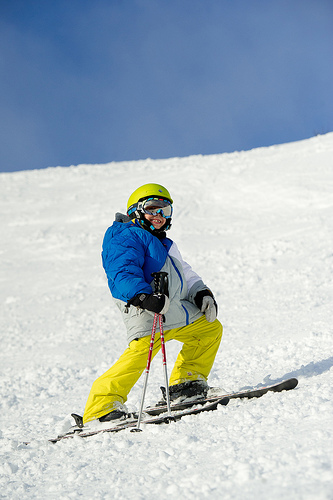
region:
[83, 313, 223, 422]
Ski pants are yellow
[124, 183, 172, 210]
Helmet is yellow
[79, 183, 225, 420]
Young boy holding ski pole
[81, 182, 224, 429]
Young boy standing in skis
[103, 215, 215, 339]
Jacket is blue and gray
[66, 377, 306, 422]
Long ski in snow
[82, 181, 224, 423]
Young boy is smiling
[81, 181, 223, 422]
Young man is smiling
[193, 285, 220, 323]
Glove is gray and black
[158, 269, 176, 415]
Ski pole is gray and red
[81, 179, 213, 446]
a child in the snow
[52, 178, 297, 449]
a child on skis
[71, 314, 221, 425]
yellow snow pants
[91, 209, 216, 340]
a blue and grey winter coat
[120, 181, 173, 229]
a hard yellow helmet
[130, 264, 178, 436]
two red and silver ski poles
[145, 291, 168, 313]
a black and white winter glove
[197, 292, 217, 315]
a black and white winter glove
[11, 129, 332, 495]
a white snowy hill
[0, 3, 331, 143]
a clear blue sky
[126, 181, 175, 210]
lime colored helmet on the young skiers head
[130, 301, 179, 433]
two ski poles in the snow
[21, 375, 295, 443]
skis attached to the boy's feet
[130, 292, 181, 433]
silver and red poles in the boy's hand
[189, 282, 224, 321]
black and gray gloves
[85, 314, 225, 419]
yellow pants on the skier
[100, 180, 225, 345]
skier wearing a blue and gray coat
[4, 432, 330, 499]
snow on the ground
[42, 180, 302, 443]
young person on skis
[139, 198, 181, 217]
goggles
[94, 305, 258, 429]
Skier wearing yellow pants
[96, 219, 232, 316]
Skier wearing blue jacket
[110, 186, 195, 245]
Skier wearing yellow helmet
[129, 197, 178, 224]
Skier wearing blue goggles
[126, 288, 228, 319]
Skier wearing ski gloves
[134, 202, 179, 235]
Skier has a big smile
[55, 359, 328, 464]
Skis and boots are black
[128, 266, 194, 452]
Two red ski poles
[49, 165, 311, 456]
A lot of snow on the ground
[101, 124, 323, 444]
Large hill covered with snow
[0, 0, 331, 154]
the sky is blue.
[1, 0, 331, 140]
the sky is clear.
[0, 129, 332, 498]
snow covering the ground.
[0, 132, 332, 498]
the snow is white.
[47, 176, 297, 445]
the kid is skiing.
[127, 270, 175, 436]
child holding ski poles.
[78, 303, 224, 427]
child's pants are yellow.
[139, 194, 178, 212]
goggles on child's face.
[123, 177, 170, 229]
child wearing a helmet.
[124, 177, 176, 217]
the helmet is yellow.